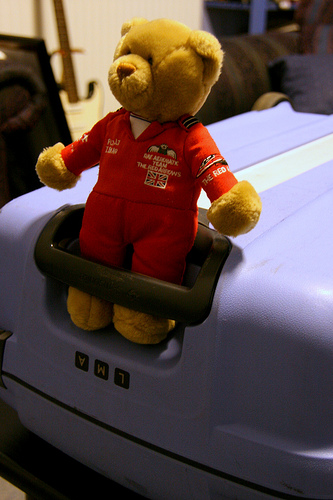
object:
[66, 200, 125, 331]
leg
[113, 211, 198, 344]
leg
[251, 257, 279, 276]
scratch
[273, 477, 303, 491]
mark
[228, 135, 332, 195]
stripe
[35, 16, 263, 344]
doll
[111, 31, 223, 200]
teddybear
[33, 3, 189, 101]
wall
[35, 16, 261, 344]
bear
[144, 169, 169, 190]
logo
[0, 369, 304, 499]
stripe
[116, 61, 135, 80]
nose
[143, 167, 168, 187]
flag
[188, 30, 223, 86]
ear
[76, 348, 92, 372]
letters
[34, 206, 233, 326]
handle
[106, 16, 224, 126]
head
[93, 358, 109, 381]
letter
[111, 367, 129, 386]
letter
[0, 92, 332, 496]
luggage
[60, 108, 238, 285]
aviation suit